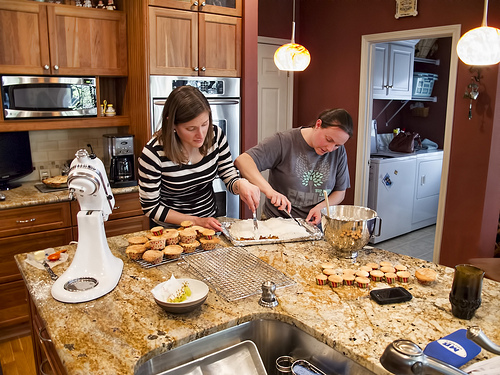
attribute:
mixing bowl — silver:
[316, 203, 379, 261]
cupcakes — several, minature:
[306, 247, 448, 305]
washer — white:
[374, 151, 416, 242]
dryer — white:
[417, 144, 443, 229]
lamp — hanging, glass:
[269, 6, 309, 78]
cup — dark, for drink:
[448, 262, 489, 323]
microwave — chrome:
[1, 53, 116, 128]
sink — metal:
[129, 313, 385, 374]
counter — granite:
[2, 161, 143, 215]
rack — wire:
[178, 243, 305, 299]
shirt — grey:
[239, 123, 352, 229]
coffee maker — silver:
[102, 132, 138, 187]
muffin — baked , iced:
[148, 238, 165, 248]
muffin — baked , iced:
[180, 230, 197, 242]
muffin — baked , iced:
[327, 274, 341, 288]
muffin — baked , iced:
[415, 268, 434, 284]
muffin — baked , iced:
[199, 238, 219, 250]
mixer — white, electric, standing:
[47, 145, 124, 302]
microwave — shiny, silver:
[0, 75, 101, 121]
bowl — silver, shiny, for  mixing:
[320, 205, 382, 259]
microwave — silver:
[1, 74, 96, 119]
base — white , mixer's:
[43, 248, 124, 305]